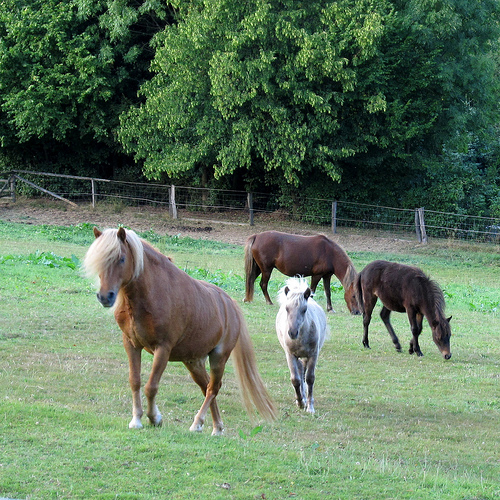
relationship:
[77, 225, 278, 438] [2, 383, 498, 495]
horse walking up a hill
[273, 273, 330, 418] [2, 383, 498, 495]
horse walking up a hill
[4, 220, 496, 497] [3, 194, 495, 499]
grass in a field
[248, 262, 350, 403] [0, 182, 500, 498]
horse trotting up a hill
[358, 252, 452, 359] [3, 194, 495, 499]
horse grazing in a field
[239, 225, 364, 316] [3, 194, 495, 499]
horse grazing in a field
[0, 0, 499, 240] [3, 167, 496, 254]
trees behind a fence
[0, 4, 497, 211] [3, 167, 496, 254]
tree limbs hanging over a fence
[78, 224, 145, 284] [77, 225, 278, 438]
hair on a horse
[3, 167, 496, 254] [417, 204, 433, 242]
fence on a poles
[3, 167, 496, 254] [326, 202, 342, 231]
fence on a poles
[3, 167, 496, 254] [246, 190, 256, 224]
fence on a poles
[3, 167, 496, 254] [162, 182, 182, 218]
fence on a poles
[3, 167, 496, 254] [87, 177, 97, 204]
fence on a poles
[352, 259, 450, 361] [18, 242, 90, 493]
horse in field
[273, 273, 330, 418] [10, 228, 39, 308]
horse trotting field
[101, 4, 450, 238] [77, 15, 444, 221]
trees in background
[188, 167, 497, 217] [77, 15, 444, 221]
bush in background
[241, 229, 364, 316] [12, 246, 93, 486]
horse in field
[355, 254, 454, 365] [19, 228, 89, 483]
horse in field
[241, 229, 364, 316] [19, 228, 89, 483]
horse in field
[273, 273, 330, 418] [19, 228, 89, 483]
horse in field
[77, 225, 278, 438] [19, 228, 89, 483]
horse in field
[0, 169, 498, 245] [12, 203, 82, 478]
fence on field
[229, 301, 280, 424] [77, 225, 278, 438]
tail on horse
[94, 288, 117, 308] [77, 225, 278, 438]
nose on horse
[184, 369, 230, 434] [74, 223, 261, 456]
legs on horse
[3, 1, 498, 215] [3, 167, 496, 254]
trees behind fence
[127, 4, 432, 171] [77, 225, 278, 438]
trees behind horse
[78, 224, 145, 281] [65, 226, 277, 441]
hair on horse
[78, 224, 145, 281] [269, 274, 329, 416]
hair on horse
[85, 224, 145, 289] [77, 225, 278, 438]
mane on horse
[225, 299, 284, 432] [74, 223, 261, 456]
tail on horse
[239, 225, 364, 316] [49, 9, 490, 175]
horse by trees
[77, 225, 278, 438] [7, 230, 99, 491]
horse in field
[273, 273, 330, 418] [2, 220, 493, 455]
horse in field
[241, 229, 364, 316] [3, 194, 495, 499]
horse in field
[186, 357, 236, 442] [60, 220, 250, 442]
leg on horse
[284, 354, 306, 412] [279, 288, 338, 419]
leg on horse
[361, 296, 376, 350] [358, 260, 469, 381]
leg on horse